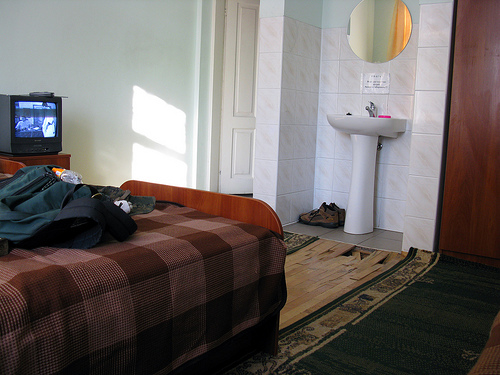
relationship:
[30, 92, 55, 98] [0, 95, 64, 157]
remote control on tv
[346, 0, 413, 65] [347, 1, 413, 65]
mirror shaped like a circle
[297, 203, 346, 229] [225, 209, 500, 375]
shoes are on floor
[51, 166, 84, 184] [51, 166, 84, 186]
package of underwear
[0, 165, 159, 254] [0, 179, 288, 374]
pile on bed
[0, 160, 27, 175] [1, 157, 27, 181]
foot of bed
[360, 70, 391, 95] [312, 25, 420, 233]
sign on wall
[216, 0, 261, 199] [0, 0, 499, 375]
door in room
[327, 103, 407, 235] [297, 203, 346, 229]
sink near shoes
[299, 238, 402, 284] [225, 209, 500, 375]
broken area of floor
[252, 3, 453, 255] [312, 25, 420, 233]
tile on wall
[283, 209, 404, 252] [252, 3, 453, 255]
floor has tile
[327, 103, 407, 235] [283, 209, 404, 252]
sink attached to floor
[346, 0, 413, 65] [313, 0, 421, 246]
mirror attached to wall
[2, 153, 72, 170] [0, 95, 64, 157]
table under tv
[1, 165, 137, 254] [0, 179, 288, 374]
backpack on bed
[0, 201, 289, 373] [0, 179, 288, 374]
comforter on bed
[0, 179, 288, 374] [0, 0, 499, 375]
bed in room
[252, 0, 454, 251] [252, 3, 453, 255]
wall covered with tile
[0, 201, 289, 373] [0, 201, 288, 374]
comforter has color maroon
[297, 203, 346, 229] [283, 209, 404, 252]
shoes on floor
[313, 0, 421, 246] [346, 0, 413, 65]
wall behind mirror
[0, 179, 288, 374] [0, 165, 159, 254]
bed has a pile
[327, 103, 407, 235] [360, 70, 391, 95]
sink under sign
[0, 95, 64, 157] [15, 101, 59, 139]
tv has a screen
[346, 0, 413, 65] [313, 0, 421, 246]
mirror hanging on wall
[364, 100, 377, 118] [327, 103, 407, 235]
faucet for sink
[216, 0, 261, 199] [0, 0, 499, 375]
door to room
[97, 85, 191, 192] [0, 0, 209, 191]
light on wall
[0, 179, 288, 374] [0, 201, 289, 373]
bed has a comforter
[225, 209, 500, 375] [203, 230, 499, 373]
floor has a rug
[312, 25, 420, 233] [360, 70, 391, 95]
wall has a sign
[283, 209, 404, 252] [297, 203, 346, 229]
floor under shoes